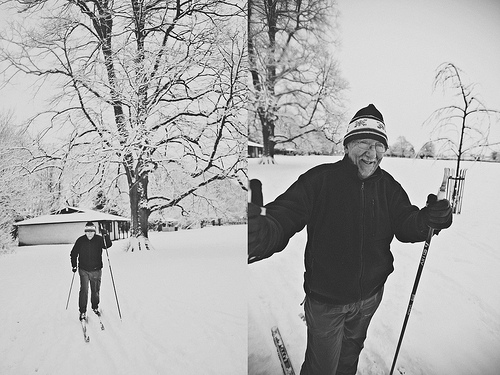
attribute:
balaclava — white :
[81, 225, 99, 230]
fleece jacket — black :
[255, 159, 453, 297]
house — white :
[14, 207, 134, 239]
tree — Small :
[415, 47, 482, 194]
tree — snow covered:
[17, 5, 226, 245]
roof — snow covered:
[10, 201, 129, 228]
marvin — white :
[342, 103, 389, 148]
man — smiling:
[249, 101, 447, 373]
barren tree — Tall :
[3, 0, 249, 235]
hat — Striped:
[342, 102, 390, 151]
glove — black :
[419, 192, 454, 237]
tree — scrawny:
[423, 59, 495, 217]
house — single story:
[15, 205, 136, 250]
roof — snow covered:
[13, 207, 122, 230]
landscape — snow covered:
[1, 144, 499, 374]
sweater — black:
[255, 164, 445, 311]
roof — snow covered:
[17, 207, 120, 225]